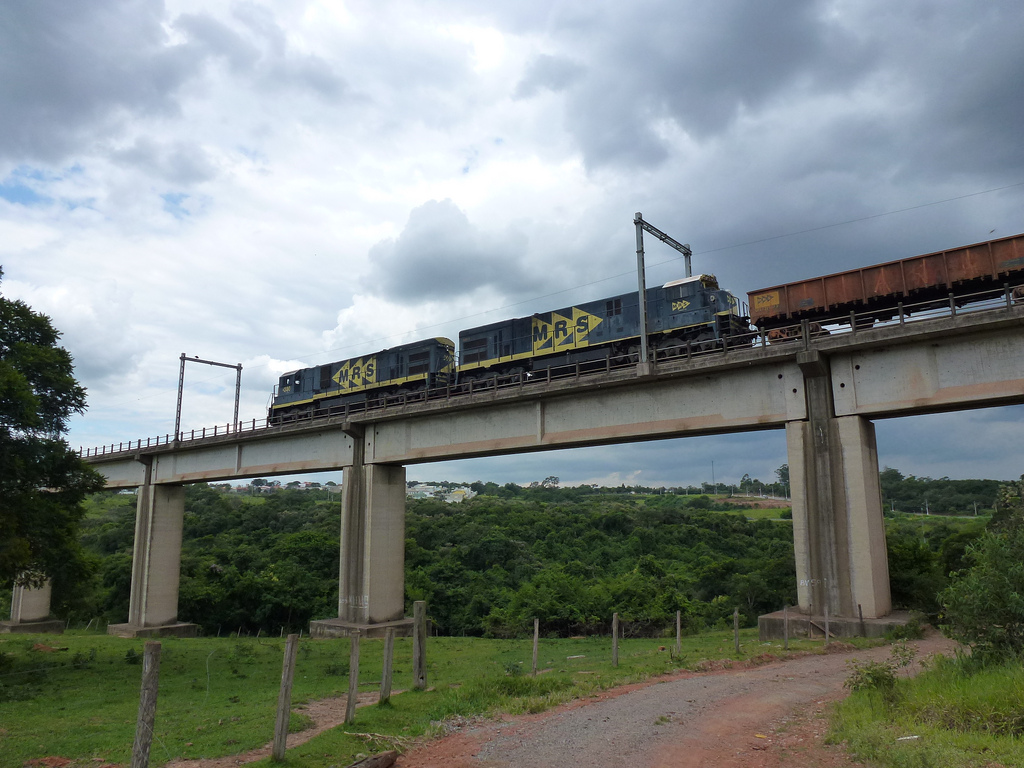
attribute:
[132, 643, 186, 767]
post — brown, wooden, fence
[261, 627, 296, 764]
post — brown, wooden, fence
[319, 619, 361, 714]
post — brown, wooden, fence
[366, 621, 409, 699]
post — brown, wooden, fence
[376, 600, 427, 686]
post — brown, wooden, fence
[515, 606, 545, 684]
post — brown, wooden, fence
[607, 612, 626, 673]
post — brown, wooden, fence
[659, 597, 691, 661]
post — brown, wooden, fence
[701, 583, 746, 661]
post — brown, wooden, fence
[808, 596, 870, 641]
post — brown, wooden, fence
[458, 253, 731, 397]
locomotive — second